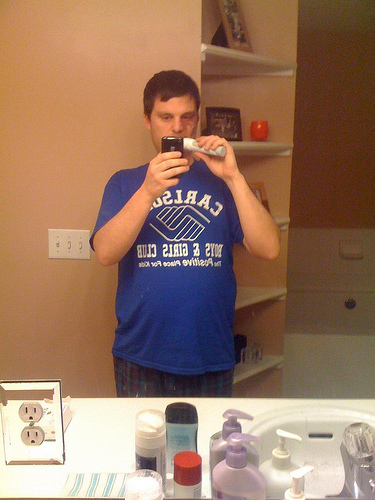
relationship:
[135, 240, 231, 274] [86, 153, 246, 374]
writing on shirt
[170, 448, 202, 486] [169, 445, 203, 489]
cap on bottle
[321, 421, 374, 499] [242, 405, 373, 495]
faucet over dirty sink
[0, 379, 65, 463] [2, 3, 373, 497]
outlet on mirror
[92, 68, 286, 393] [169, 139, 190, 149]
man brushing teeth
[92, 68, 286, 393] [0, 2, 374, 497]
man in bathroom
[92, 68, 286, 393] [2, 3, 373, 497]
man in mirror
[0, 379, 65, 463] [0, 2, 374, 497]
outlet in bathroom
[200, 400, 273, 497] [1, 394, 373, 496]
lotion on counter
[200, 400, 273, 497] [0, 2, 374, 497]
lotion in bathroom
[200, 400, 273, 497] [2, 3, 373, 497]
lotion in mirror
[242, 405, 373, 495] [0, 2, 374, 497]
dirty sink in bathroom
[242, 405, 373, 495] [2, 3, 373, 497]
dirty sink in mirror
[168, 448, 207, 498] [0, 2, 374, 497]
shaving cream in bathroom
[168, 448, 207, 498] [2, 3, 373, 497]
shaving cream in mirror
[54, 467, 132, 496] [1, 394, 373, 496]
towel on counter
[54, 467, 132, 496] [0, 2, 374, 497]
towel in bathroom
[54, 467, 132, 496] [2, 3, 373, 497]
towel in mirror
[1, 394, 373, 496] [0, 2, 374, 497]
counter in bathroom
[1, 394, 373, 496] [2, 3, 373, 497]
counter in mirror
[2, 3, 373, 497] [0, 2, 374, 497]
mirror in bathroom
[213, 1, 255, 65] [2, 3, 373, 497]
picture in mirror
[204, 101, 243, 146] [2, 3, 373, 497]
picture in mirror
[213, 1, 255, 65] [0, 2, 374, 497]
picture in bathroom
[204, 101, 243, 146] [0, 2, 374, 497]
picture in bathroom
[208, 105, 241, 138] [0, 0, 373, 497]
picture in mirror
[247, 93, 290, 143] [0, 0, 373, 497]
candle in mirror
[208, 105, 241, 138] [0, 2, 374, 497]
picture in bathroom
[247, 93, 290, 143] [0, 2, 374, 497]
candle in bathroom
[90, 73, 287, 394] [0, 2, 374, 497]
bathtub reflecting in bathroom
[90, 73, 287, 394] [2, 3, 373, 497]
bathtub reflecting in mirror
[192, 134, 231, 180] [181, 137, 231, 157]
hand holding toothbrush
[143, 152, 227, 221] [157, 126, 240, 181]
hand holding cellphone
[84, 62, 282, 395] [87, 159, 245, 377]
boy wearing shirt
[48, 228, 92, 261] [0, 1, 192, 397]
light switches on wall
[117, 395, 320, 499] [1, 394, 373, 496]
toiletries on counter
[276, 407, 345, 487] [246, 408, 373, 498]
faucet to sink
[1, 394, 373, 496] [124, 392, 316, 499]
counter has bottles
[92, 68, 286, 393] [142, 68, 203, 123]
man has hair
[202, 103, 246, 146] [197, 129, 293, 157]
picture frame on shelf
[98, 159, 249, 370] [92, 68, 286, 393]
shirt of man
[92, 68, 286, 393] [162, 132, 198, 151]
man brushing teeth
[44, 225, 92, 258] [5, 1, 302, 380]
light switches on wall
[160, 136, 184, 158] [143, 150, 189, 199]
cell phone in hand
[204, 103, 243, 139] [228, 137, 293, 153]
frane on shelf